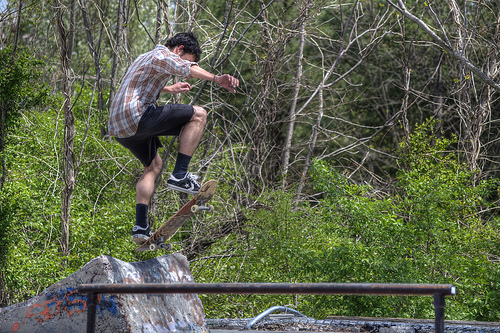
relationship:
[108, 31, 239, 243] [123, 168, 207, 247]
man wears black shoes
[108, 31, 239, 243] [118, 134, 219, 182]
man wears sock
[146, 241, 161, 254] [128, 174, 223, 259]
wheel on skateboard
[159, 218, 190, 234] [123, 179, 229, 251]
designs on skateboard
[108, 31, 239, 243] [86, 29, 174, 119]
man wears shirt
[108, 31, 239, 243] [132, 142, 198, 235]
man wears shoes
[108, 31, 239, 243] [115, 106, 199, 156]
man wears shorts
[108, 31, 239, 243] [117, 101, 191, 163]
man wears shorts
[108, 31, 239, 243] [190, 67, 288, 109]
man has arms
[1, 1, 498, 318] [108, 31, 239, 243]
forest behind man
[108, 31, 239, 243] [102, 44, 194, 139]
man wearing shirt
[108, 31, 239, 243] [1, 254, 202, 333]
man skateboarding over man rock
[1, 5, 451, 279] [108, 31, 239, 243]
forest skateboarding  behind man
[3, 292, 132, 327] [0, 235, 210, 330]
graffiti painted on rock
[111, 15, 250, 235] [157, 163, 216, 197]
man wearing converse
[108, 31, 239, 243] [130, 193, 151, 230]
man wearing socks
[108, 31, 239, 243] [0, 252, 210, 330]
man skateboarding over rocks